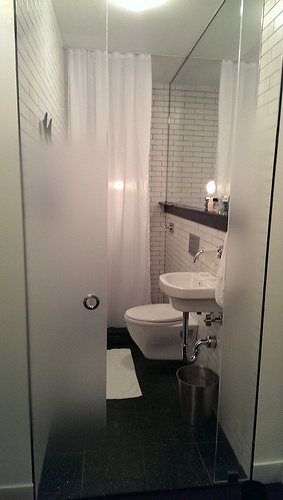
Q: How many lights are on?
A: 1 light is on.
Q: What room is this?
A: The bathroom.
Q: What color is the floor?
A: The floor is black.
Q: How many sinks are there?
A: 1 sink.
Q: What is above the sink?
A: A mirror.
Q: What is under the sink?
A: A garbage can.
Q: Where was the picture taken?
A: In the bathroom.